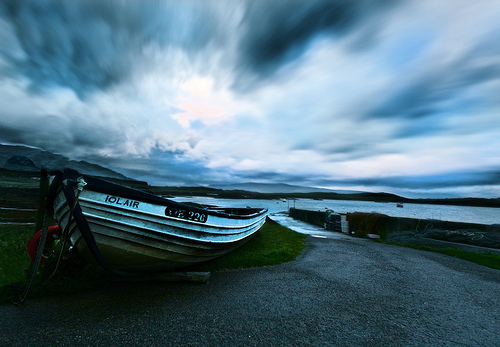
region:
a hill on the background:
[156, 180, 496, 205]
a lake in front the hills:
[177, 183, 497, 222]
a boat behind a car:
[0, 153, 276, 300]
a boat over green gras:
[74, 179, 315, 280]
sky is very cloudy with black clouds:
[1, 3, 493, 177]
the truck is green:
[0, 158, 92, 305]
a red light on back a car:
[29, 214, 69, 244]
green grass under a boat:
[219, 217, 310, 266]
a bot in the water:
[390, 198, 412, 210]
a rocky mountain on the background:
[2, 140, 133, 176]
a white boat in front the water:
[70, 173, 425, 270]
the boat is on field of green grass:
[76, 169, 311, 279]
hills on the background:
[159, 177, 496, 202]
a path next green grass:
[261, 202, 362, 259]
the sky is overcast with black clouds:
[2, 5, 495, 180]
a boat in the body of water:
[385, 196, 412, 213]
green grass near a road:
[245, 217, 408, 294]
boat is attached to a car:
[3, 159, 108, 299]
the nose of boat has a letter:
[83, 177, 157, 220]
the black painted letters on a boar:
[106, 193, 139, 211]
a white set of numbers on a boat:
[163, 200, 201, 227]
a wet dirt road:
[77, 203, 491, 345]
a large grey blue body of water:
[169, 192, 491, 232]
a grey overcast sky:
[4, 4, 494, 203]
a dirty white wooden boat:
[78, 179, 266, 271]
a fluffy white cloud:
[153, 136, 200, 167]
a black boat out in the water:
[393, 199, 405, 208]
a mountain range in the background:
[1, 143, 132, 185]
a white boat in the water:
[280, 195, 287, 202]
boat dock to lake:
[272, 211, 299, 226]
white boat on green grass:
[83, 184, 275, 256]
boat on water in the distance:
[392, 199, 407, 209]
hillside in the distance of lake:
[165, 185, 402, 200]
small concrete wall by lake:
[415, 237, 486, 257]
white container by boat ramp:
[327, 211, 348, 233]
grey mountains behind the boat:
[1, 144, 118, 174]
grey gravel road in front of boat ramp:
[312, 239, 422, 308]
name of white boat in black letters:
[99, 191, 143, 210]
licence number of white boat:
[160, 204, 210, 226]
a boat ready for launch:
[50, 161, 281, 263]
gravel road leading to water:
[320, 257, 466, 330]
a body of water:
[418, 199, 483, 219]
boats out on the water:
[234, 192, 414, 212]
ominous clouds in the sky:
[65, 60, 433, 151]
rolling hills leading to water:
[4, 133, 111, 175]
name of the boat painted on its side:
[103, 192, 143, 211]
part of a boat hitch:
[31, 169, 91, 287]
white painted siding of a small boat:
[105, 213, 175, 243]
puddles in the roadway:
[292, 223, 310, 234]